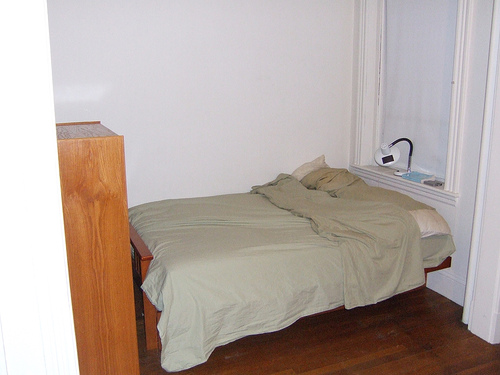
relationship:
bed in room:
[129, 154, 455, 372] [0, 1, 499, 374]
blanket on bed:
[127, 173, 425, 371] [129, 154, 455, 372]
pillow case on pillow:
[337, 183, 436, 210] [410, 207, 452, 238]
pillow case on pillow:
[300, 167, 369, 196] [292, 155, 330, 180]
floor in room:
[134, 277, 499, 374] [0, 1, 499, 374]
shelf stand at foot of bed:
[55, 121, 141, 374] [129, 154, 455, 372]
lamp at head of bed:
[374, 137, 413, 176] [129, 154, 455, 372]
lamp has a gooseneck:
[374, 137, 413, 176] [389, 137, 414, 172]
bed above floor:
[129, 154, 455, 372] [134, 277, 499, 374]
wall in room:
[47, 0, 355, 210] [0, 1, 499, 374]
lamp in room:
[374, 137, 413, 176] [0, 1, 499, 374]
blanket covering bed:
[127, 173, 425, 371] [129, 154, 455, 372]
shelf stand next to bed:
[55, 121, 141, 374] [129, 154, 455, 372]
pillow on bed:
[410, 207, 452, 238] [129, 154, 455, 372]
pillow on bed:
[292, 155, 330, 180] [129, 154, 455, 372]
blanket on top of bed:
[127, 173, 425, 371] [129, 154, 455, 372]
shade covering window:
[378, 0, 458, 181] [351, 0, 475, 205]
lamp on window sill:
[374, 137, 413, 176] [350, 162, 461, 207]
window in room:
[351, 0, 475, 205] [0, 1, 499, 374]